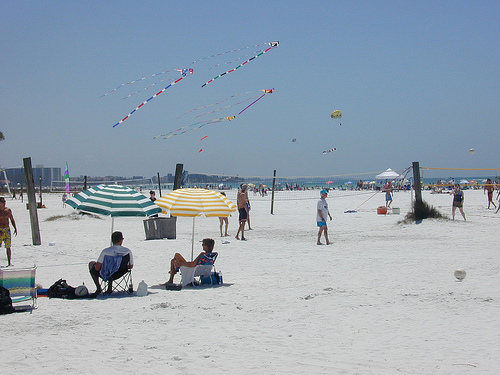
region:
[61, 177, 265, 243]
Two umbrellas next to each other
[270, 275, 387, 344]
Tracks in the sand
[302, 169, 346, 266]
Man standing on beach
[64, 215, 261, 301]
People sitting under umbrellas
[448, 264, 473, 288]
Volley ball on the beach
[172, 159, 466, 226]
Volley ball net on beach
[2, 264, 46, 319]
Lawn chair on the beach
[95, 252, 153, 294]
Camper chair on the sand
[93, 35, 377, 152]
Kites flying in the sky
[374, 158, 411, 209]
White umbrella in the sand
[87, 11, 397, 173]
kites flying in the air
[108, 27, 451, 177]
kites in the air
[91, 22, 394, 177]
kites flying high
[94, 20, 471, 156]
kites flying high in the air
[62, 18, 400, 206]
kites with long tails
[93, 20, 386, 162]
multiple kites flying in the air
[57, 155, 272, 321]
two large beach umbrellas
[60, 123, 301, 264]
two striped beach umbrellas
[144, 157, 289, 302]
a yellow striped beach umbrella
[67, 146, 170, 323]
a green striped beach umbrella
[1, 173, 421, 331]
people on the beach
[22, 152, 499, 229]
volleyball nets set up between thick posts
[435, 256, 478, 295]
a ball on the sand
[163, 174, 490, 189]
blue ocean in the distance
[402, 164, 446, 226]
foliage growing near post's base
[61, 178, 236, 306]
two people sitting in chairs beneath umbrellas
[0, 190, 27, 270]
a man wearing swim trunks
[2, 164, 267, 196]
buildings near the water's edge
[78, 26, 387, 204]
kites of various sizes and shapes in the air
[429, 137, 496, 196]
a volley ball flying over a net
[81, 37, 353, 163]
a whole bunch of kites flying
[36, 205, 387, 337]
people are relaxing on the beach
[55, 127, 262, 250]
the umbrellas have colorful stripes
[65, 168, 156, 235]
this one is green & white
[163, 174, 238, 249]
this one is yellow & white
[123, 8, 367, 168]
the kites are all very colorful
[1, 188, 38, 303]
this man is wearing yellow shorts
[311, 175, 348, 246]
this lady is wearing a blue hat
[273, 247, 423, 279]
the sand is a beautiful white color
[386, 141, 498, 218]
people playing volley ball.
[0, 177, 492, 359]
A large number of people on a beach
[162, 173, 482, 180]
The ocean is visible behind the beach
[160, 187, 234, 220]
The woman's umbrella has yellow stripes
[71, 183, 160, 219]
The man's umbrella has green stripes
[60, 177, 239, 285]
A couple sit beneath their umbrellas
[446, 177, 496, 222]
People playing beach volleyball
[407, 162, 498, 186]
A volleyball net set up on the beach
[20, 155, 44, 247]
Wooden poles line the beach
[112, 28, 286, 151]
Many kites are flying in the sky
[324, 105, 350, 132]
A parasailer with a yellow parachute